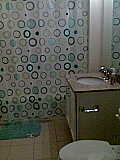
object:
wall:
[8, 3, 66, 89]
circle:
[28, 95, 35, 102]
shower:
[0, 0, 120, 160]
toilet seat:
[58, 139, 120, 159]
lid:
[58, 138, 116, 159]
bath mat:
[0, 119, 41, 139]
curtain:
[0, 0, 90, 120]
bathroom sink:
[78, 75, 103, 86]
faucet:
[98, 66, 108, 80]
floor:
[0, 114, 70, 159]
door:
[68, 86, 76, 141]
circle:
[63, 28, 69, 36]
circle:
[26, 63, 32, 70]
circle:
[23, 29, 30, 37]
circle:
[63, 62, 70, 69]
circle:
[39, 54, 45, 61]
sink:
[77, 75, 105, 84]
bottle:
[110, 67, 117, 86]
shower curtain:
[0, 0, 89, 121]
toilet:
[57, 138, 120, 159]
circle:
[16, 104, 24, 111]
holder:
[84, 106, 99, 114]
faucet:
[106, 67, 118, 87]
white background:
[0, 0, 88, 117]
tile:
[2, 138, 43, 158]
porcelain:
[56, 137, 119, 159]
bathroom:
[1, 0, 119, 159]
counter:
[65, 73, 118, 143]